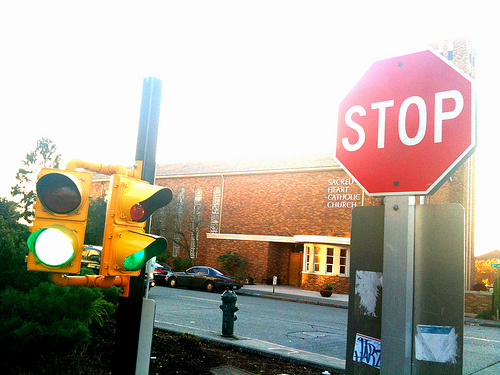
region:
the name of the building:
[320, 173, 357, 219]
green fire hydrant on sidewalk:
[220, 285, 242, 343]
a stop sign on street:
[341, 32, 470, 192]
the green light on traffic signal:
[25, 219, 86, 271]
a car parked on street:
[168, 261, 238, 290]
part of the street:
[271, 296, 342, 353]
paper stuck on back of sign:
[350, 265, 385, 323]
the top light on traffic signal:
[33, 167, 91, 221]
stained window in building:
[208, 180, 219, 234]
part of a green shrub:
[10, 289, 87, 353]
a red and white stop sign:
[329, 44, 471, 196]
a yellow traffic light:
[21, 158, 163, 291]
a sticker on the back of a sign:
[355, 327, 384, 372]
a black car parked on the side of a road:
[158, 261, 248, 302]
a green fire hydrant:
[208, 285, 248, 338]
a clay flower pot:
[310, 282, 337, 302]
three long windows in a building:
[166, 176, 228, 260]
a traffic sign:
[317, 46, 467, 371]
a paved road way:
[154, 293, 332, 339]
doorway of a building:
[281, 230, 319, 292]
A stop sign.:
[328, 47, 479, 221]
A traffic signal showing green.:
[24, 156, 100, 296]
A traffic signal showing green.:
[99, 169, 170, 305]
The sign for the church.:
[325, 173, 363, 221]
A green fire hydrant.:
[217, 288, 245, 341]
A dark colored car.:
[163, 259, 246, 298]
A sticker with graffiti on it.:
[349, 333, 379, 373]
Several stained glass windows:
[170, 187, 222, 267]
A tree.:
[10, 131, 65, 231]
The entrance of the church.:
[288, 250, 307, 289]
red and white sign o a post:
[312, 41, 487, 203]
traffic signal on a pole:
[15, 142, 175, 313]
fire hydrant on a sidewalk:
[210, 283, 246, 345]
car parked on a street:
[158, 260, 250, 299]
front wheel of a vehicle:
[163, 271, 183, 292]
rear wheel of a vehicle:
[201, 278, 219, 295]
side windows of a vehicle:
[181, 265, 212, 277]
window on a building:
[186, 181, 204, 263]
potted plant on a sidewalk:
[312, 278, 338, 303]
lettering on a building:
[324, 173, 365, 215]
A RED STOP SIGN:
[324, 43, 474, 199]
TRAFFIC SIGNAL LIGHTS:
[22, 154, 169, 304]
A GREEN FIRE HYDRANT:
[209, 283, 248, 345]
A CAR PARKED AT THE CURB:
[163, 263, 252, 293]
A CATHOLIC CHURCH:
[162, 157, 369, 299]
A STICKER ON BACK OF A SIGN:
[346, 328, 400, 374]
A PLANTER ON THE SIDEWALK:
[310, 280, 345, 303]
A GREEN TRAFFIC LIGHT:
[23, 217, 94, 282]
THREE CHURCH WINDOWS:
[168, 180, 235, 271]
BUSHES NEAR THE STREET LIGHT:
[1, 197, 126, 370]